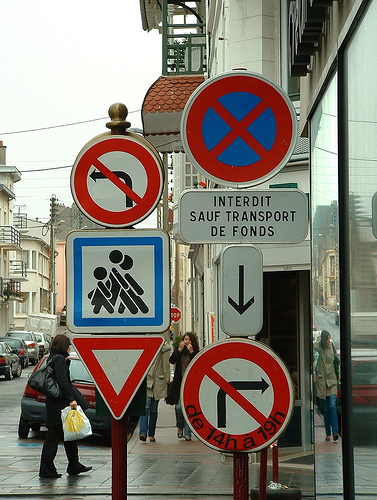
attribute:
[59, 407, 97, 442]
plastic bag — white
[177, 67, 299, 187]
sign — black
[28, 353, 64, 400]
shoulder bag — black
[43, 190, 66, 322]
telephone pole — Brown 